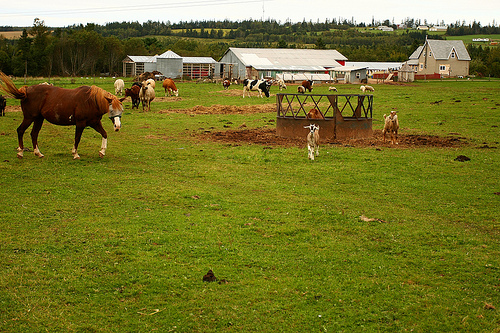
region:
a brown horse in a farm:
[2, 77, 127, 174]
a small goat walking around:
[298, 115, 323, 160]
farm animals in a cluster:
[108, 73, 163, 113]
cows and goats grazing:
[215, 70, 385, 107]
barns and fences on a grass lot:
[120, 45, 418, 93]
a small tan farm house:
[401, 33, 471, 83]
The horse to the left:
[7, 68, 161, 170]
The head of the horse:
[106, 95, 133, 128]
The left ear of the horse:
[103, 88, 118, 104]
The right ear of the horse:
[118, 93, 133, 104]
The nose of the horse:
[111, 120, 125, 130]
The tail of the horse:
[1, 73, 24, 98]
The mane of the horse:
[85, 80, 121, 107]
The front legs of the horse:
[67, 121, 118, 161]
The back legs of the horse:
[10, 115, 55, 161]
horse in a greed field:
[13, 81, 126, 161]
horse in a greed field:
[113, 76, 125, 99]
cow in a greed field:
[159, 76, 182, 99]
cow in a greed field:
[241, 78, 269, 97]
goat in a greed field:
[303, 121, 325, 162]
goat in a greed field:
[378, 108, 401, 145]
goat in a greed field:
[328, 83, 337, 88]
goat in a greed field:
[356, 83, 368, 92]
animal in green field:
[0, 69, 127, 164]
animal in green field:
[111, 77, 125, 98]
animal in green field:
[120, 83, 135, 107]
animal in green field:
[138, 80, 155, 115]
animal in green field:
[160, 76, 180, 98]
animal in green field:
[241, 75, 273, 98]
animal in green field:
[222, 75, 232, 90]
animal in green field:
[303, 123, 323, 159]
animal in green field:
[379, 108, 401, 146]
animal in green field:
[357, 83, 369, 92]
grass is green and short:
[223, 193, 354, 283]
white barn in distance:
[228, 48, 331, 73]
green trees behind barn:
[33, 16, 310, 78]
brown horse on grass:
[6, 88, 118, 165]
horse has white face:
[96, 102, 130, 163]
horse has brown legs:
[66, 117, 108, 162]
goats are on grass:
[286, 116, 407, 166]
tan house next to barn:
[391, 43, 486, 106]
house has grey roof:
[423, 31, 464, 69]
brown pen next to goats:
[268, 91, 390, 151]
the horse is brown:
[7, 68, 137, 180]